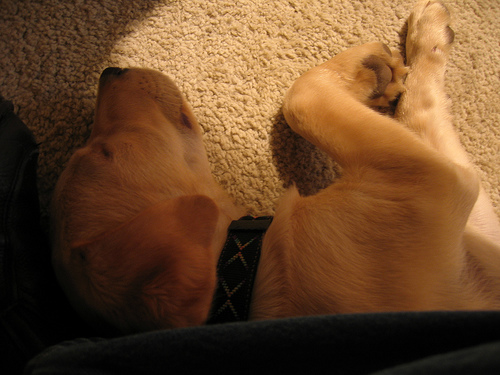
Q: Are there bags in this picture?
A: No, there are no bags.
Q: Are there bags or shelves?
A: No, there are no bags or shelves.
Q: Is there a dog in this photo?
A: Yes, there is a dog.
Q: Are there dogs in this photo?
A: Yes, there is a dog.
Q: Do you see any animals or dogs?
A: Yes, there is a dog.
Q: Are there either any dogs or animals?
A: Yes, there is a dog.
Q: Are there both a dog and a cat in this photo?
A: No, there is a dog but no cats.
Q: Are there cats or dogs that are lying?
A: Yes, the dog is lying.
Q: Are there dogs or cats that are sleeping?
A: Yes, the dog is sleeping.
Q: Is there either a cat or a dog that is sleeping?
A: Yes, the dog is sleeping.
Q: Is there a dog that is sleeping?
A: Yes, there is a dog that is sleeping.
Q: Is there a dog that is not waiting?
A: Yes, there is a dog that is sleeping.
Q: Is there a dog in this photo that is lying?
A: Yes, there is a dog that is lying.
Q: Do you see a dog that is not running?
A: Yes, there is a dog that is lying .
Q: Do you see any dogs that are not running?
A: Yes, there is a dog that is lying .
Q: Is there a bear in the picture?
A: No, there are no bears.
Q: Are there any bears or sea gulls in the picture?
A: No, there are no bears or sea gulls.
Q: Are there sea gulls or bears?
A: No, there are no bears or sea gulls.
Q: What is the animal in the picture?
A: The animal is a dog.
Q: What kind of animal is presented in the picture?
A: The animal is a dog.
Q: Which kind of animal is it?
A: The animal is a dog.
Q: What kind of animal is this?
A: This is a dog.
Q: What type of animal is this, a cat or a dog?
A: This is a dog.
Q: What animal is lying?
A: The animal is a dog.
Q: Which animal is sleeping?
A: The animal is a dog.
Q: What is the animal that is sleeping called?
A: The animal is a dog.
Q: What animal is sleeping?
A: The animal is a dog.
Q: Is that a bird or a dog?
A: That is a dog.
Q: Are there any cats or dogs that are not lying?
A: No, there is a dog but it is lying.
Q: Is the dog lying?
A: Yes, the dog is lying.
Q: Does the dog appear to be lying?
A: Yes, the dog is lying.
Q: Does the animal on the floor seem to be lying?
A: Yes, the dog is lying.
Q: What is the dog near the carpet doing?
A: The dog is lying.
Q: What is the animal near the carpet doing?
A: The dog is lying.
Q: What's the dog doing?
A: The dog is lying.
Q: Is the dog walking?
A: No, the dog is lying.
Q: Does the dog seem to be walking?
A: No, the dog is lying.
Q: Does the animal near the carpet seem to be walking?
A: No, the dog is lying.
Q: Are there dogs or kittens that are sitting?
A: No, there is a dog but it is lying.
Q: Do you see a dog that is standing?
A: No, there is a dog but it is lying.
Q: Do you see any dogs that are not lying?
A: No, there is a dog but it is lying.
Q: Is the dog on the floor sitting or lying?
A: The dog is lying.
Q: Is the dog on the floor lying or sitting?
A: The dog is lying.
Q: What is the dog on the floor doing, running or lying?
A: The dog is lying.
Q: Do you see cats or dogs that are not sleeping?
A: No, there is a dog but it is sleeping.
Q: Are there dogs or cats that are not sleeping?
A: No, there is a dog but it is sleeping.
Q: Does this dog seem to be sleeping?
A: Yes, the dog is sleeping.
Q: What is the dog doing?
A: The dog is sleeping.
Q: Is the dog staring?
A: No, the dog is sleeping.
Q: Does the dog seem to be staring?
A: No, the dog is sleeping.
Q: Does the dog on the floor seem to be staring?
A: No, the dog is sleeping.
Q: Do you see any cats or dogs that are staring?
A: No, there is a dog but it is sleeping.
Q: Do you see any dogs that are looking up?
A: No, there is a dog but it is sleeping.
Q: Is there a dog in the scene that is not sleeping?
A: No, there is a dog but it is sleeping.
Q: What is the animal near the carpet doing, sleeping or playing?
A: The dog is sleeping.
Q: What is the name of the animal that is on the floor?
A: The animal is a dog.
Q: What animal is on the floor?
A: The animal is a dog.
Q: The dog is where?
A: The dog is on the floor.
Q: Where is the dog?
A: The dog is on the floor.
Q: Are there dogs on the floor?
A: Yes, there is a dog on the floor.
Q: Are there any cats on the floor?
A: No, there is a dog on the floor.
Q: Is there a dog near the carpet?
A: Yes, there is a dog near the carpet.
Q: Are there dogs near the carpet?
A: Yes, there is a dog near the carpet.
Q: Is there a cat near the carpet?
A: No, there is a dog near the carpet.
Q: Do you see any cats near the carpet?
A: No, there is a dog near the carpet.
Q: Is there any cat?
A: No, there are no cats.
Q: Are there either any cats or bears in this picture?
A: No, there are no cats or bears.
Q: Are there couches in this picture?
A: No, there are no couches.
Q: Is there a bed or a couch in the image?
A: No, there are no couches or beds.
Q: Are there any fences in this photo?
A: No, there are no fences.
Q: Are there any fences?
A: No, there are no fences.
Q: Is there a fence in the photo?
A: No, there are no fences.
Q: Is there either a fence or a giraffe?
A: No, there are no fences or giraffes.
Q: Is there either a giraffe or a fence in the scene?
A: No, there are no fences or giraffes.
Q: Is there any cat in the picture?
A: No, there are no cats.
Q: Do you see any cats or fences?
A: No, there are no cats or fences.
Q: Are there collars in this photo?
A: Yes, there is a collar.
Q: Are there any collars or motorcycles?
A: Yes, there is a collar.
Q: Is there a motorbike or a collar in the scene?
A: Yes, there is a collar.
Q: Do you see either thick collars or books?
A: Yes, there is a thick collar.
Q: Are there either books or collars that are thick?
A: Yes, the collar is thick.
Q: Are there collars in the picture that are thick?
A: Yes, there is a thick collar.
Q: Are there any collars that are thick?
A: Yes, there is a collar that is thick.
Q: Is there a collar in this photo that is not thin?
A: Yes, there is a thick collar.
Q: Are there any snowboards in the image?
A: No, there are no snowboards.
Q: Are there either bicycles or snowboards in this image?
A: No, there are no snowboards or bicycles.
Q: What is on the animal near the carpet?
A: The collar is on the dog.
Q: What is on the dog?
A: The collar is on the dog.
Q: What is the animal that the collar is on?
A: The animal is a dog.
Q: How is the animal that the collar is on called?
A: The animal is a dog.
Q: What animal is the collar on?
A: The collar is on the dog.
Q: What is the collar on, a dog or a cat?
A: The collar is on a dog.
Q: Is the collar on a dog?
A: Yes, the collar is on a dog.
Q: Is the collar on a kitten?
A: No, the collar is on a dog.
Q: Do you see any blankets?
A: No, there are no blankets.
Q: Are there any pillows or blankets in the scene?
A: No, there are no blankets or pillows.